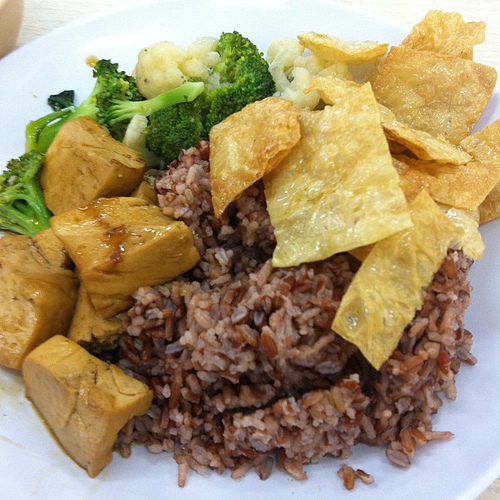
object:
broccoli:
[1, 30, 280, 234]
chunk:
[5, 235, 72, 382]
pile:
[122, 143, 475, 485]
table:
[4, 2, 144, 86]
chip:
[330, 186, 458, 371]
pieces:
[329, 458, 368, 495]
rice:
[88, 140, 478, 488]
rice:
[130, 265, 446, 465]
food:
[8, 42, 483, 467]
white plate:
[40, 15, 200, 80]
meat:
[25, 142, 240, 453]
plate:
[1, 0, 498, 498]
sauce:
[88, 198, 160, 273]